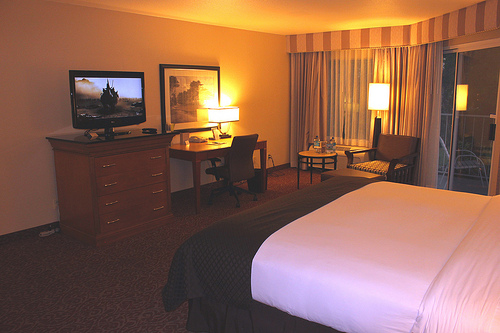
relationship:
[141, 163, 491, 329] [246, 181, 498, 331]
bed with sheets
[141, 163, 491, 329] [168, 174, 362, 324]
bed with blanket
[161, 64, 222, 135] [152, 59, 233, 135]
picture in frame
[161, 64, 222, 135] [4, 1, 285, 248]
picture on wall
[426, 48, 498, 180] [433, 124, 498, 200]
doors leading out to patio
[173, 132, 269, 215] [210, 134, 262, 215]
desk with a chair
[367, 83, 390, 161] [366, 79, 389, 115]
floor lamp with lamp shade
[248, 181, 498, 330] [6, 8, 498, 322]
bedding in a hotel room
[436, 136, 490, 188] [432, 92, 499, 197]
chair outside on a deck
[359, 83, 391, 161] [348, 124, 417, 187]
floor lamp next to an armchair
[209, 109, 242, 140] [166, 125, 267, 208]
lamp on desk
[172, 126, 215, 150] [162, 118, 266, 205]
telephone on desk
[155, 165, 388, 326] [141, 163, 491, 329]
bedskirt on bed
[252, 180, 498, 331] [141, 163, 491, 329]
sheet on bed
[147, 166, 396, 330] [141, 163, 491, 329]
bedspread on bed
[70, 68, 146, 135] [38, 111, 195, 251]
television on top of dresser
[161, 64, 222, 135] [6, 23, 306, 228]
picture on wall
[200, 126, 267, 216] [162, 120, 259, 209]
chair under desk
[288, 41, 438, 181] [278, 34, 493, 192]
curtain over windows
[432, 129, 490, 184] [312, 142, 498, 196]
chair on deck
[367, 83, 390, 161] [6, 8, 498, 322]
floor lamp in hotel room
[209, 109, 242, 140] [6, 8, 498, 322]
lamp in hotel room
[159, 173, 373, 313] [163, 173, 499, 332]
sheet on bed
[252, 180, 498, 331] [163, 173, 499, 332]
sheet on bed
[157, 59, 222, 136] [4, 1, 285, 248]
picture hanging on wall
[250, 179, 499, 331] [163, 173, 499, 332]
blanket on bed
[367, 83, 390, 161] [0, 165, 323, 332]
floor lamp on floor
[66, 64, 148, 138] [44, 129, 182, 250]
television sitting on cabinets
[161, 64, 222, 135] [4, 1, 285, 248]
picture hanging on wall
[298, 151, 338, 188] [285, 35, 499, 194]
deck next to window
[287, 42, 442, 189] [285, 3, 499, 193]
curtain hanging on window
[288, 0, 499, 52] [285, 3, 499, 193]
valance hanging above window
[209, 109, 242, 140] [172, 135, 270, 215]
lamp on desk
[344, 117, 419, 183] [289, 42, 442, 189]
armchair resting against curtains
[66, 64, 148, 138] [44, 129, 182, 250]
television on cabinets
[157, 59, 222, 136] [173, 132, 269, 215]
picture above desk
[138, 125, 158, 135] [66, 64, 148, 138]
remote next to television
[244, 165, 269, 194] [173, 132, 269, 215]
trash can next to desk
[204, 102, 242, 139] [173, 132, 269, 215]
lamp on desk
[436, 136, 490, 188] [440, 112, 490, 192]
chair on balcony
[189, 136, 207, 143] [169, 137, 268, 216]
telephone on desk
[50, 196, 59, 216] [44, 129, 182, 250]
outlet behind cabinets